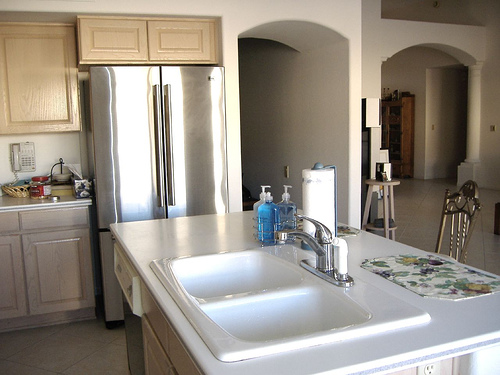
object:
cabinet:
[78, 15, 219, 65]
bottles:
[253, 185, 296, 243]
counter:
[109, 208, 497, 375]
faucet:
[276, 214, 356, 287]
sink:
[150, 247, 427, 361]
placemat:
[360, 252, 500, 300]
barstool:
[362, 179, 401, 240]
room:
[0, 0, 500, 375]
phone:
[11, 141, 36, 171]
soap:
[253, 185, 297, 242]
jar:
[31, 176, 52, 199]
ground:
[392, 179, 500, 273]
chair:
[433, 179, 482, 265]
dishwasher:
[122, 251, 145, 375]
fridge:
[88, 62, 226, 329]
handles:
[151, 84, 175, 209]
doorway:
[236, 19, 351, 227]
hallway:
[236, 21, 348, 224]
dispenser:
[300, 162, 337, 251]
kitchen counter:
[110, 204, 500, 374]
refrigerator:
[91, 67, 229, 327]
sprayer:
[331, 238, 349, 287]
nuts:
[29, 181, 51, 199]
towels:
[298, 169, 334, 244]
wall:
[0, 4, 500, 335]